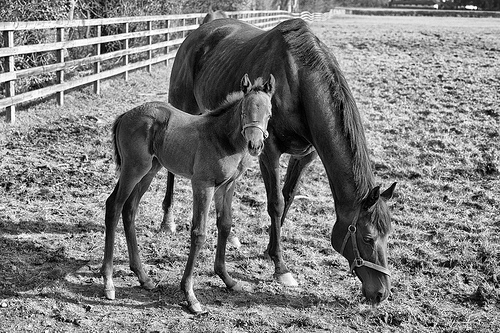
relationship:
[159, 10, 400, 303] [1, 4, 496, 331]
mare eating in fenced area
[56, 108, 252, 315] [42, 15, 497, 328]
foal in area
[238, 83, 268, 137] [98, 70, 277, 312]
halter on horse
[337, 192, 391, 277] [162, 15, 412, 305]
halter on horse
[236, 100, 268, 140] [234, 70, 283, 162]
halter on head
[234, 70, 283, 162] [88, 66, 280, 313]
head of foal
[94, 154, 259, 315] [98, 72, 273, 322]
legs of foal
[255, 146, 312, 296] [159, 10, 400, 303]
legs of mare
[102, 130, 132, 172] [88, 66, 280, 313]
tail of foal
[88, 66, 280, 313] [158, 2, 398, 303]
foal with mother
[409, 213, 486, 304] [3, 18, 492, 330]
grass on field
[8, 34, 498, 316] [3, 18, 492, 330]
grass on field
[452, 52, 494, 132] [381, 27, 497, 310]
grass on field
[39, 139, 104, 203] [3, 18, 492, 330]
grass on field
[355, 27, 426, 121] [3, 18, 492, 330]
grass on field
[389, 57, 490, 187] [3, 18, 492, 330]
grass on field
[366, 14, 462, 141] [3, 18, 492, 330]
grass on field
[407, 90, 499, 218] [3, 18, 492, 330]
grass on field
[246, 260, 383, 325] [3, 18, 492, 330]
grass on field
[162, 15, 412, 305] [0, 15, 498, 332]
horse eating grass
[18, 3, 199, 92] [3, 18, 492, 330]
fence next to field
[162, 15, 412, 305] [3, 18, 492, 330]
horse in field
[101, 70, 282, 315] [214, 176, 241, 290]
colt has leg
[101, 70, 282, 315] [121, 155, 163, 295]
colt has leg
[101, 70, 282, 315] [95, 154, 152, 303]
colt has leg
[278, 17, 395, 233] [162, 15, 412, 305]
mane on horse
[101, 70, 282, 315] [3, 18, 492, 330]
colt standing in field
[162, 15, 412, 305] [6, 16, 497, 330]
horse standing in pasture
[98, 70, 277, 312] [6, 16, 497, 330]
horse standing in pasture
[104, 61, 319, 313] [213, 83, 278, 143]
pony has head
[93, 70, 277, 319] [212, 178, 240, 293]
pony has leg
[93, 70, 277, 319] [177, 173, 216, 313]
pony has leg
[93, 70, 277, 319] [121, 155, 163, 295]
pony has leg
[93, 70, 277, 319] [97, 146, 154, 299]
pony has leg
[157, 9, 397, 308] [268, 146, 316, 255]
horse has leg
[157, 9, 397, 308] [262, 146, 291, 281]
horse has leg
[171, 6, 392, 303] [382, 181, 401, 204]
horse has ear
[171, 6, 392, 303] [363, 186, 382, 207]
horse has ear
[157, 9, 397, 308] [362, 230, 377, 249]
horse has eye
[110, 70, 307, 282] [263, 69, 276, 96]
pony has ear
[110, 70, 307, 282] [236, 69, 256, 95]
pony has ear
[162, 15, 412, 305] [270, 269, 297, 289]
horse has hoof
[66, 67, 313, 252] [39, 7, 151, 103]
foal in fenced area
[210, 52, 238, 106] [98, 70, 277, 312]
rib protruding from horse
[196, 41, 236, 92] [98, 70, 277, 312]
rib protruding from horse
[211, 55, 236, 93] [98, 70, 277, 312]
rib protruding from horse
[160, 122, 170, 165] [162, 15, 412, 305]
rib protruding from horse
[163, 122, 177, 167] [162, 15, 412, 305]
rib protruding from horse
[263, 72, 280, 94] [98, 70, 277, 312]
ear belonging to horse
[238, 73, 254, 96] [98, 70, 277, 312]
ear belonging to horse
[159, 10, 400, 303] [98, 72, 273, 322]
mare standing next to foal